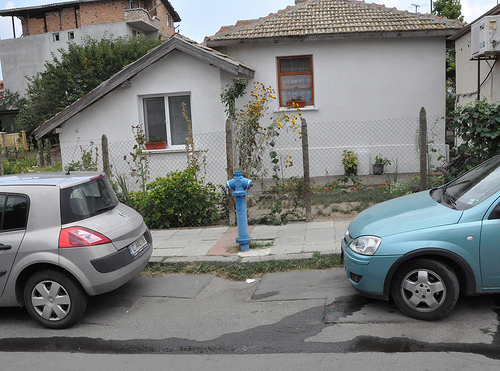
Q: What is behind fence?
A: House.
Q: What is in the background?
A: House.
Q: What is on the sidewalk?
A: Street.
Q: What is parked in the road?
A: Car.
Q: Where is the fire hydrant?
A: On the sidewalk.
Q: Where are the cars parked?
A: Near the sidewalk.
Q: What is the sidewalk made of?
A: Concrete pavers.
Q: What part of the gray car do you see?
A: The back.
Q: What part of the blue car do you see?
A: The front.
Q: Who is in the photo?
A: Nobody is.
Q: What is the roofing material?
A: Tiles.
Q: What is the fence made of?
A: Chicken wire.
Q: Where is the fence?
A: In front of the house.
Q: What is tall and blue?
A: Hydrant.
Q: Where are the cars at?
A: Parked on road.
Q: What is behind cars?
A: Houses.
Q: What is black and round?
A: The tires.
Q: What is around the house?
A: Fence.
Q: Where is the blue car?
A: To the right.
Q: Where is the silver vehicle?
A: To the left.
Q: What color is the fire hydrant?
A: Blue.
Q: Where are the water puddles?
A: Road.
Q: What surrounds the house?
A: Fence.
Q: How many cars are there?
A: 2.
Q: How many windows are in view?
A: 2.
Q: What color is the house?
A: Gray.